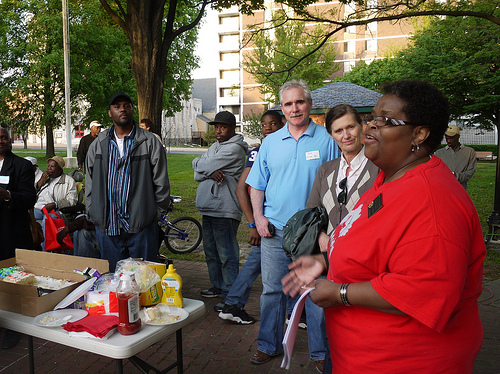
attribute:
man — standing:
[83, 89, 177, 280]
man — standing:
[187, 111, 250, 301]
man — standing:
[244, 79, 330, 373]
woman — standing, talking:
[267, 79, 488, 374]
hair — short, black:
[377, 74, 449, 153]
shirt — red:
[321, 156, 486, 374]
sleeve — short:
[367, 223, 460, 334]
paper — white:
[275, 279, 324, 373]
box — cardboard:
[0, 248, 117, 318]